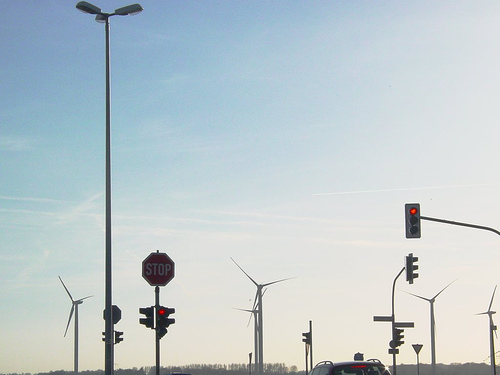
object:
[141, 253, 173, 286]
sign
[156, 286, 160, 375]
pole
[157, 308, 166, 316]
light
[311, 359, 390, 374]
car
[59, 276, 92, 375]
wind mill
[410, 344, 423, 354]
sign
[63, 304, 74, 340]
propeller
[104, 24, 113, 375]
pole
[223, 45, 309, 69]
sky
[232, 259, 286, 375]
wind mill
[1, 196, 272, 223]
trail